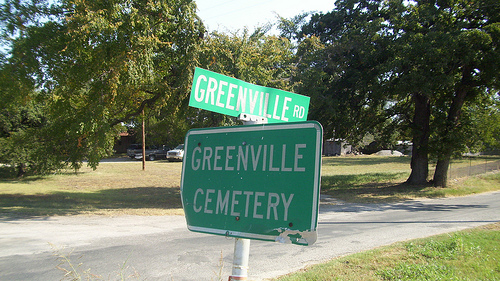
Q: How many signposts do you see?
A: One.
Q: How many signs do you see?
A: Two.